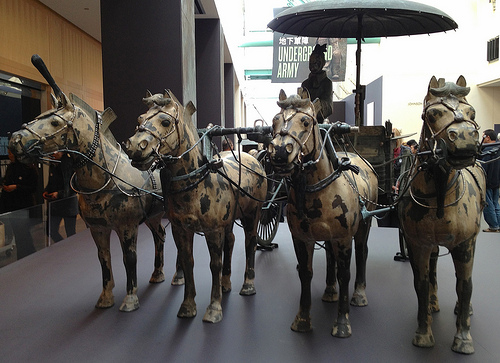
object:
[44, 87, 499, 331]
horses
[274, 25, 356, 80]
sign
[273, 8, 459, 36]
umbrella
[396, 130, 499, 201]
people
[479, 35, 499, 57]
vent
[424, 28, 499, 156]
wall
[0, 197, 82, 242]
shield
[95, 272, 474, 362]
hooves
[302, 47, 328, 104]
man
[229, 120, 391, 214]
carriage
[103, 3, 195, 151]
pillar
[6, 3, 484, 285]
room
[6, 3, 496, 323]
museum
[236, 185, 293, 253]
wheel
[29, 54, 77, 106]
halter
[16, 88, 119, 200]
headshot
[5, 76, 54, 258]
entrance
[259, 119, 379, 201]
chariot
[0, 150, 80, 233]
pedestrians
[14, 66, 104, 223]
hallway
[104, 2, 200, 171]
column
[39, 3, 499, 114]
roof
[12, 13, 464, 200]
background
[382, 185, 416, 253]
wheel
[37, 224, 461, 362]
ground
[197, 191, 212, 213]
black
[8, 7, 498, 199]
building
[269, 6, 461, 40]
black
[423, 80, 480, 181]
head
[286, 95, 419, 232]
wagon